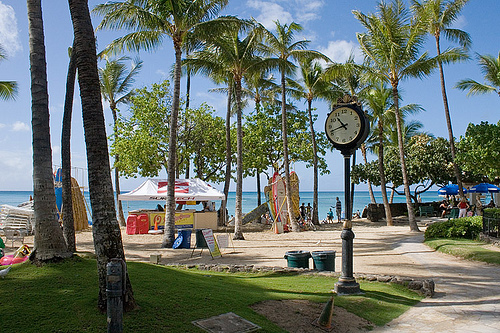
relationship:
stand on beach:
[115, 175, 228, 232] [0, 189, 485, 269]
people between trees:
[324, 192, 344, 223] [283, 58, 375, 223]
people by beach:
[351, 208, 364, 221] [0, 189, 485, 269]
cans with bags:
[284, 248, 338, 270] [284, 247, 337, 257]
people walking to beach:
[434, 192, 484, 216] [0, 189, 485, 269]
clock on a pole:
[323, 103, 371, 155] [334, 151, 358, 290]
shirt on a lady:
[457, 201, 467, 207] [455, 196, 469, 220]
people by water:
[298, 195, 360, 225] [1, 190, 496, 226]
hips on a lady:
[458, 207, 468, 210] [455, 196, 469, 219]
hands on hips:
[458, 205, 468, 210] [458, 207, 468, 210]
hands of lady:
[458, 205, 468, 210] [455, 196, 469, 219]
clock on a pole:
[315, 103, 376, 150] [343, 158, 358, 288]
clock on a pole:
[323, 103, 371, 155] [344, 165, 352, 285]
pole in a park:
[344, 165, 352, 285] [5, 17, 455, 327]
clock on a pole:
[323, 103, 371, 155] [335, 153, 360, 294]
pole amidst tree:
[335, 153, 360, 294] [374, 1, 430, 211]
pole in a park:
[335, 153, 360, 294] [21, 2, 481, 324]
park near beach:
[21, 2, 481, 324] [316, 189, 339, 202]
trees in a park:
[148, 18, 298, 164] [5, 17, 455, 327]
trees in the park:
[152, 1, 258, 85] [5, 17, 455, 327]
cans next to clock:
[310, 250, 337, 272] [323, 95, 363, 154]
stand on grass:
[337, 146, 357, 281] [296, 270, 315, 293]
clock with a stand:
[323, 103, 371, 155] [337, 146, 357, 281]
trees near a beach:
[173, 12, 463, 96] [330, 182, 341, 196]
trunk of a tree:
[85, 149, 120, 252] [61, 1, 141, 251]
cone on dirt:
[311, 290, 338, 330] [290, 298, 302, 326]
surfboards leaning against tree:
[47, 163, 89, 225] [62, 139, 71, 160]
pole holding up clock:
[335, 153, 360, 294] [327, 99, 366, 151]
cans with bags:
[286, 240, 338, 275] [288, 245, 300, 255]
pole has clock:
[335, 153, 360, 294] [326, 92, 365, 149]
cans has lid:
[310, 250, 337, 272] [308, 245, 338, 257]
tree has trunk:
[57, 3, 142, 331] [66, 6, 137, 305]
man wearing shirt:
[330, 194, 346, 221] [334, 201, 342, 214]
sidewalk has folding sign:
[132, 224, 344, 283] [192, 228, 226, 268]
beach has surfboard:
[1, 181, 484, 236] [271, 173, 291, 233]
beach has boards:
[1, 181, 484, 236] [263, 171, 288, 236]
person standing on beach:
[297, 198, 309, 224] [0, 173, 481, 238]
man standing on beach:
[333, 194, 341, 224] [0, 173, 481, 238]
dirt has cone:
[259, 293, 369, 329] [309, 293, 337, 331]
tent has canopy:
[114, 167, 237, 234] [120, 176, 227, 205]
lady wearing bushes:
[455, 196, 469, 220] [424, 215, 484, 239]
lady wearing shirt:
[455, 196, 469, 220] [452, 198, 467, 209]